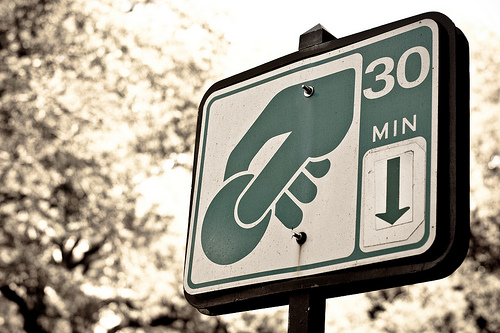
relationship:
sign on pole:
[178, 12, 453, 307] [287, 279, 327, 327]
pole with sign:
[287, 279, 327, 327] [178, 12, 453, 307]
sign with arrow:
[178, 12, 453, 307] [357, 147, 426, 242]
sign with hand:
[178, 12, 453, 307] [221, 73, 344, 227]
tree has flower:
[54, 67, 147, 193] [29, 105, 157, 246]